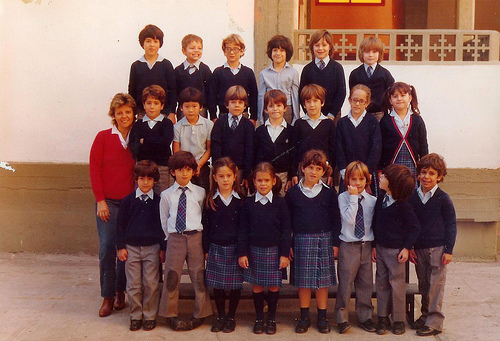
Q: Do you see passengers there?
A: No, there are no passengers.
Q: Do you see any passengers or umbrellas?
A: No, there are no passengers or umbrellas.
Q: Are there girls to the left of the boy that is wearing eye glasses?
A: Yes, there are girls to the left of the boy.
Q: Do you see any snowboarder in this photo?
A: No, there are no snowboarders.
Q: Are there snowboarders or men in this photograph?
A: No, there are no snowboarders or men.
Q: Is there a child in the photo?
A: Yes, there are children.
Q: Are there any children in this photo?
A: Yes, there are children.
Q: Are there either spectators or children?
A: Yes, there are children.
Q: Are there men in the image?
A: No, there are no men.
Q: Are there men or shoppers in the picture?
A: No, there are no men or shoppers.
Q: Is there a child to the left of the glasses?
A: Yes, there are children to the left of the glasses.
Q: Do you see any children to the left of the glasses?
A: Yes, there are children to the left of the glasses.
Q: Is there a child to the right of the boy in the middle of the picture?
A: Yes, there are children to the right of the boy.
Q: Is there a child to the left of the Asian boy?
A: No, the children are to the right of the boy.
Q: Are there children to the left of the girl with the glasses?
A: Yes, there are children to the left of the girl.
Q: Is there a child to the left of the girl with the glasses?
A: Yes, there are children to the left of the girl.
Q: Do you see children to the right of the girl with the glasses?
A: No, the children are to the left of the girl.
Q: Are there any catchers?
A: No, there are no catchers.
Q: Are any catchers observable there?
A: No, there are no catchers.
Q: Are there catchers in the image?
A: No, there are no catchers.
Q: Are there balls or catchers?
A: No, there are no catchers or balls.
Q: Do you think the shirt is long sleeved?
A: Yes, the shirt is long sleeved.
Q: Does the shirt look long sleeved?
A: Yes, the shirt is long sleeved.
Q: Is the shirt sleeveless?
A: No, the shirt is long sleeved.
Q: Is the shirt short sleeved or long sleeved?
A: The shirt is long sleeved.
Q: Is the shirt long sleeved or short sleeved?
A: The shirt is long sleeved.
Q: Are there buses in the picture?
A: No, there are no buses.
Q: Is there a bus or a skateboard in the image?
A: No, there are no buses or skateboards.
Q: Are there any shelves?
A: No, there are no shelves.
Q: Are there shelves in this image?
A: No, there are no shelves.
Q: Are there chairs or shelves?
A: No, there are no shelves or chairs.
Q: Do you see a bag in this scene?
A: No, there are no bags.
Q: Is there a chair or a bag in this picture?
A: No, there are no bags or chairs.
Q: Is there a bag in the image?
A: No, there are no bags.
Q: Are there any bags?
A: No, there are no bags.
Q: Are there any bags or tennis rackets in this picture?
A: No, there are no bags or tennis rackets.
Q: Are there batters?
A: No, there are no batters.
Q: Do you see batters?
A: No, there are no batters.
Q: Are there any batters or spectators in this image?
A: No, there are no batters or spectators.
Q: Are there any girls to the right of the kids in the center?
A: Yes, there is a girl to the right of the kids.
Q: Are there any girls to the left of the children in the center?
A: No, the girl is to the right of the kids.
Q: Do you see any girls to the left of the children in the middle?
A: No, the girl is to the right of the kids.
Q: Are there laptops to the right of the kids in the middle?
A: No, there is a girl to the right of the children.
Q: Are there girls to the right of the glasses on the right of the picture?
A: Yes, there is a girl to the right of the glasses.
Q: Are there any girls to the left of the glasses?
A: No, the girl is to the right of the glasses.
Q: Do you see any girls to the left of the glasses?
A: No, the girl is to the right of the glasses.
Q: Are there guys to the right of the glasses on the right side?
A: No, there is a girl to the right of the glasses.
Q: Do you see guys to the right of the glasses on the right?
A: No, there is a girl to the right of the glasses.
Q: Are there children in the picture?
A: Yes, there is a child.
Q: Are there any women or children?
A: Yes, there is a child.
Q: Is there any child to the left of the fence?
A: Yes, there is a child to the left of the fence.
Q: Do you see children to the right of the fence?
A: No, the child is to the left of the fence.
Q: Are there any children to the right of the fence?
A: No, the child is to the left of the fence.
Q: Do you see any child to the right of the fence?
A: No, the child is to the left of the fence.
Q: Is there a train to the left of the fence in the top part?
A: No, there is a child to the left of the fence.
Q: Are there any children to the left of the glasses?
A: Yes, there is a child to the left of the glasses.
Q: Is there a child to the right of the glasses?
A: No, the child is to the left of the glasses.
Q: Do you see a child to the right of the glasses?
A: No, the child is to the left of the glasses.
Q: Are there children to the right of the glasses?
A: No, the child is to the left of the glasses.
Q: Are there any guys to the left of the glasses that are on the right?
A: No, there is a child to the left of the glasses.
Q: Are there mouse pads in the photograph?
A: No, there are no mouse pads.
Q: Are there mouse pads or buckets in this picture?
A: No, there are no mouse pads or buckets.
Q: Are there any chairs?
A: No, there are no chairs.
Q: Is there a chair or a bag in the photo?
A: No, there are no chairs or bags.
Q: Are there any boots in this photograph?
A: Yes, there are boots.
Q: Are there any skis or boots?
A: Yes, there are boots.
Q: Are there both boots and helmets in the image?
A: No, there are boots but no helmets.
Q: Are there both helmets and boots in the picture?
A: No, there are boots but no helmets.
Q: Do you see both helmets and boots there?
A: No, there are boots but no helmets.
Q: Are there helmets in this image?
A: No, there are no helmets.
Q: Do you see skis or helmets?
A: No, there are no helmets or skis.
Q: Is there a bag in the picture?
A: No, there are no bags.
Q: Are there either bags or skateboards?
A: No, there are no bags or skateboards.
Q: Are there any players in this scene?
A: No, there are no players.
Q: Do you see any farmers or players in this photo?
A: No, there are no players or farmers.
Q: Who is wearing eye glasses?
A: The boy is wearing eye glasses.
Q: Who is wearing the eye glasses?
A: The boy is wearing eye glasses.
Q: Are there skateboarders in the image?
A: No, there are no skateboarders.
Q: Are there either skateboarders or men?
A: No, there are no skateboarders or men.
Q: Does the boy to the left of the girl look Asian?
A: Yes, the boy is asian.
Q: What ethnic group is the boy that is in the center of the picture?
A: The boy is asian.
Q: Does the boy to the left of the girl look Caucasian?
A: No, the boy is asian.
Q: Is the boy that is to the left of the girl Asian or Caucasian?
A: The boy is asian.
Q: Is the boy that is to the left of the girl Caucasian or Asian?
A: The boy is asian.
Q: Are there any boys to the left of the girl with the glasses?
A: Yes, there is a boy to the left of the girl.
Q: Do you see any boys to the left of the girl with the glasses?
A: Yes, there is a boy to the left of the girl.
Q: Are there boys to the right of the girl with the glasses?
A: No, the boy is to the left of the girl.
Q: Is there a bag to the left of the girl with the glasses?
A: No, there is a boy to the left of the girl.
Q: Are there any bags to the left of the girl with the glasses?
A: No, there is a boy to the left of the girl.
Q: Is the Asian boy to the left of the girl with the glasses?
A: Yes, the boy is to the left of the girl.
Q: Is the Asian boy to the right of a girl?
A: No, the boy is to the left of a girl.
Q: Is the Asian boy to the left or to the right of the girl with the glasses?
A: The boy is to the left of the girl.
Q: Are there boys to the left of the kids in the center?
A: Yes, there is a boy to the left of the kids.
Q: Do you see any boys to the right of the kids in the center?
A: No, the boy is to the left of the children.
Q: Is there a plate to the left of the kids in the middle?
A: No, there is a boy to the left of the kids.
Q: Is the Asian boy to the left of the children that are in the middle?
A: Yes, the boy is to the left of the children.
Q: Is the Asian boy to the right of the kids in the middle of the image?
A: No, the boy is to the left of the children.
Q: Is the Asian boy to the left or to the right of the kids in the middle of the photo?
A: The boy is to the left of the children.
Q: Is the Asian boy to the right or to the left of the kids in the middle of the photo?
A: The boy is to the left of the children.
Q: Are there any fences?
A: Yes, there is a fence.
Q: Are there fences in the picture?
A: Yes, there is a fence.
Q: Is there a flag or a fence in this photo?
A: Yes, there is a fence.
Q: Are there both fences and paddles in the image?
A: No, there is a fence but no paddles.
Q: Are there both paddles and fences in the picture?
A: No, there is a fence but no paddles.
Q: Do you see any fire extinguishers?
A: No, there are no fire extinguishers.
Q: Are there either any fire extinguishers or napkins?
A: No, there are no fire extinguishers or napkins.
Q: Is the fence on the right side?
A: Yes, the fence is on the right of the image.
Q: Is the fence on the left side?
A: No, the fence is on the right of the image.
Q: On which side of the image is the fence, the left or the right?
A: The fence is on the right of the image.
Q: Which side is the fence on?
A: The fence is on the right of the image.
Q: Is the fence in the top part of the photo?
A: Yes, the fence is in the top of the image.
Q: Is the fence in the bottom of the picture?
A: No, the fence is in the top of the image.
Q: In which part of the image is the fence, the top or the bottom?
A: The fence is in the top of the image.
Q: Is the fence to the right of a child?
A: Yes, the fence is to the right of a child.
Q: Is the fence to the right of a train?
A: No, the fence is to the right of a child.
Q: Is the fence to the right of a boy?
A: Yes, the fence is to the right of a boy.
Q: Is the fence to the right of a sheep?
A: No, the fence is to the right of a boy.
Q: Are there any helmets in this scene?
A: No, there are no helmets.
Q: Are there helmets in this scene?
A: No, there are no helmets.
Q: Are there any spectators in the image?
A: No, there are no spectators.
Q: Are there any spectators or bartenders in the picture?
A: No, there are no spectators or bartenders.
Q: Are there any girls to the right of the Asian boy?
A: Yes, there is a girl to the right of the boy.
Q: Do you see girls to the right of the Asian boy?
A: Yes, there is a girl to the right of the boy.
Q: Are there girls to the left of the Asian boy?
A: No, the girl is to the right of the boy.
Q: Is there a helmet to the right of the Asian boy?
A: No, there is a girl to the right of the boy.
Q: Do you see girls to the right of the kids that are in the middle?
A: Yes, there is a girl to the right of the kids.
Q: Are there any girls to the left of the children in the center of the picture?
A: No, the girl is to the right of the children.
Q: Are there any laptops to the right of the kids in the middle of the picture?
A: No, there is a girl to the right of the children.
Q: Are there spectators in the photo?
A: No, there are no spectators.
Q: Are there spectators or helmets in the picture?
A: No, there are no spectators or helmets.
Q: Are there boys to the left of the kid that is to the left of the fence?
A: Yes, there is a boy to the left of the kid.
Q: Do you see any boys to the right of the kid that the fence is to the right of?
A: No, the boy is to the left of the kid.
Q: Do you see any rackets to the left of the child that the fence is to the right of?
A: No, there is a boy to the left of the child.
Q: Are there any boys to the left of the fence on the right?
A: Yes, there is a boy to the left of the fence.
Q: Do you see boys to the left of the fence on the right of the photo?
A: Yes, there is a boy to the left of the fence.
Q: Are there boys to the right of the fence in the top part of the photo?
A: No, the boy is to the left of the fence.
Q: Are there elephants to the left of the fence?
A: No, there is a boy to the left of the fence.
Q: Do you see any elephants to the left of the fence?
A: No, there is a boy to the left of the fence.